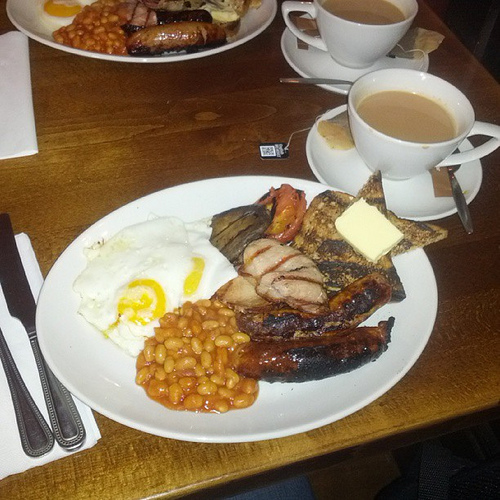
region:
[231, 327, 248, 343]
cooked brown colored bean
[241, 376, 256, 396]
cooked brown colored bean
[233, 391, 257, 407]
cooked brown colored bean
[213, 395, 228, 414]
cooked brown colored bean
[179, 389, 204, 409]
cooked brown colored bean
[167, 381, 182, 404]
cooked brown colored bean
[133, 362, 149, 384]
cooked brown colored bean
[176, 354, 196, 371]
cooked brown colored bean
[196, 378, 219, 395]
cooked brown colored bean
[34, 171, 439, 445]
Food on a white plate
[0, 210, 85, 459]
Two pieces of silverware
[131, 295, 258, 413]
Side of baked beans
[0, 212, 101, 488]
Silverware on a folded white napkin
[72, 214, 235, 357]
Eggs with two yolks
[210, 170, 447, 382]
Various grilled meats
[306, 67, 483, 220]
Cup of tea on a plate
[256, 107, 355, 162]
Used tea bag with a string a black tag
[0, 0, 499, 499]
Two plates of the same food on a wood table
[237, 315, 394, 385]
Brown well done sausage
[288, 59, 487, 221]
cup of hot tea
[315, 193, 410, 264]
pat of butter on toast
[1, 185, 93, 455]
knife and fork on white napkin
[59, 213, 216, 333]
cooked egg on white ceramic dish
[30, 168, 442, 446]
food on white ceramic plate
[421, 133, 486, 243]
spoon resting on saucer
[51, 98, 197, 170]
table top made of wood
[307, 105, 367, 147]
used tea bag on saucer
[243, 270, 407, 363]
sausages on white plate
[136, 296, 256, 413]
baked beans on plate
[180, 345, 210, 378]
beans on the plate.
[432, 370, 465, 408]
table made of wood.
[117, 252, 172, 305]
eggs on the plate.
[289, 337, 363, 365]
sausage on the plate.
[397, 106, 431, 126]
tea in the saucer.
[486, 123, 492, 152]
handle of the mug.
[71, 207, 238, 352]
Eggs on the plate.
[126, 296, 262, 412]
Beans on the plate.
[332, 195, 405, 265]
A pat of butter.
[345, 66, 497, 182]
Cup of tea on the table.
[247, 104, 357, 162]
Tea bag on the table.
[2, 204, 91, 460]
Metal silverware on the table.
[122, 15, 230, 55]
Sausage on the plate.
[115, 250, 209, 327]
Yolk on the eggs.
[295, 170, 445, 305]
toast on the plate.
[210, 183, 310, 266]
Roasted vegetables on the plate.